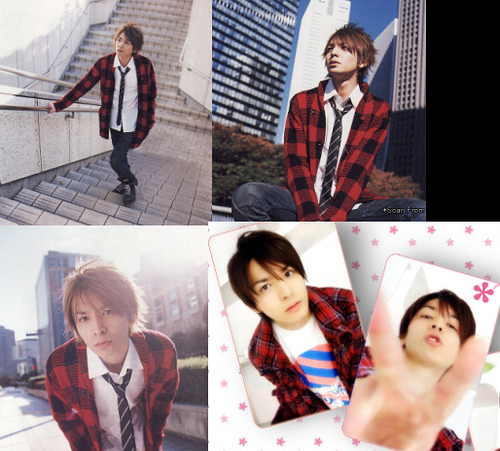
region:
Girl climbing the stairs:
[46, 19, 176, 215]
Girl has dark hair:
[106, 17, 150, 57]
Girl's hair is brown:
[98, 22, 153, 54]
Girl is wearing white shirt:
[107, 55, 140, 137]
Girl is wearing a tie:
[114, 64, 131, 131]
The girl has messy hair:
[39, 252, 184, 362]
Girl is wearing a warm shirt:
[276, 80, 383, 221]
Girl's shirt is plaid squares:
[283, 76, 381, 220]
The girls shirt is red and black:
[270, 77, 396, 215]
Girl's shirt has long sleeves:
[276, 85, 368, 225]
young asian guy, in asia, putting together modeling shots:
[2, 1, 499, 448]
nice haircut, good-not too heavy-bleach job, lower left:
[50, 255, 147, 343]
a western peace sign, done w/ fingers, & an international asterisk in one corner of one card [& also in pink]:
[344, 278, 494, 448]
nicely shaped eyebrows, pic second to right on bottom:
[246, 261, 299, 297]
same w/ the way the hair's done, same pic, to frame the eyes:
[235, 241, 315, 311]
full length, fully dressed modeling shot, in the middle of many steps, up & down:
[0, 1, 212, 227]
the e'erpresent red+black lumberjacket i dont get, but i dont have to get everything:
[23, 46, 467, 448]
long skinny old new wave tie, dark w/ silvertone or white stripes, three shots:
[84, 61, 355, 449]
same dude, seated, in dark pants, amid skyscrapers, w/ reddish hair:
[208, 0, 423, 222]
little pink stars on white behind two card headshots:
[208, 224, 498, 449]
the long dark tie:
[115, 67, 127, 127]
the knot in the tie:
[112, 382, 124, 394]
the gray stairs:
[146, 142, 207, 224]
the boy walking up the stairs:
[45, 23, 157, 209]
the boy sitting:
[237, 21, 426, 218]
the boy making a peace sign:
[366, 270, 470, 450]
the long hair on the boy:
[61, 255, 148, 325]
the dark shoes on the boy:
[114, 179, 141, 204]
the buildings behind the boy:
[218, 2, 436, 138]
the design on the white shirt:
[290, 342, 341, 405]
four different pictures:
[4, 0, 490, 441]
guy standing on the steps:
[39, 10, 169, 196]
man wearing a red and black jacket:
[52, 12, 162, 163]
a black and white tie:
[305, 90, 355, 194]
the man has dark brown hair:
[235, 219, 325, 318]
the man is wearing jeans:
[70, 107, 150, 199]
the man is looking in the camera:
[37, 257, 140, 367]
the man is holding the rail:
[2, 22, 159, 169]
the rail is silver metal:
[0, 92, 89, 122]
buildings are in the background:
[236, 5, 411, 155]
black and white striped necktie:
[106, 376, 141, 448]